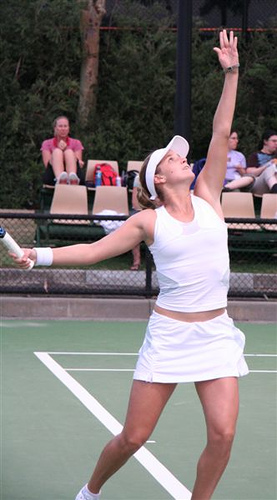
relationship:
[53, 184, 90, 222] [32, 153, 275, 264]
seat in stands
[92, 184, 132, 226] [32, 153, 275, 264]
seat in stands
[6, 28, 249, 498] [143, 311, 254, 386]
tennis player wearing skirt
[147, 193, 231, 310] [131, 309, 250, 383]
tank top above skirt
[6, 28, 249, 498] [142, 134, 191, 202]
tennis player wearing visor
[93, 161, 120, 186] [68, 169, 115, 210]
backpack sitting on chair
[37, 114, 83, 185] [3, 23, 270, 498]
woman watch tennis match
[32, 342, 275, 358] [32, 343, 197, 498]
line perpendicular to line